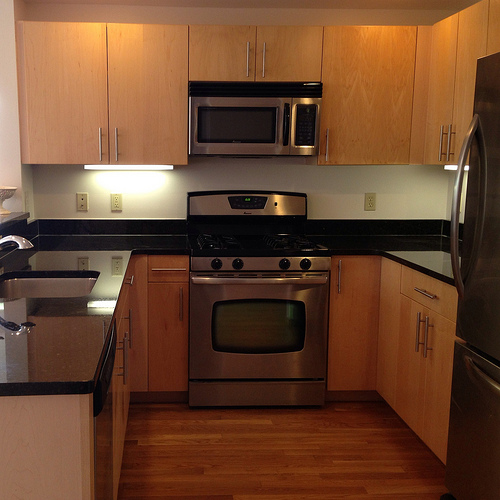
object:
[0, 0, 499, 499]
kitchen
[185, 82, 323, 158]
microwave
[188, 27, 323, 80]
cabinets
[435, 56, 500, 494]
refrigerator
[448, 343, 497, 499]
freezer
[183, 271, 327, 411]
oven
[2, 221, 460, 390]
counter top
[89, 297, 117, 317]
reflections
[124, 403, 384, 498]
floors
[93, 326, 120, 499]
dishwasher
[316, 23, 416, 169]
cabinet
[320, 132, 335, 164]
handles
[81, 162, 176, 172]
light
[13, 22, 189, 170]
cabinet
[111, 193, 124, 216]
outlet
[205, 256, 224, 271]
knobs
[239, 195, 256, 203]
writing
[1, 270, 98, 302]
sink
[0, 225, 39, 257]
faucet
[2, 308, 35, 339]
reflection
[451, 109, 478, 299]
handle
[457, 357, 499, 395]
handle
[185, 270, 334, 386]
door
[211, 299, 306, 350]
window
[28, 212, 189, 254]
counter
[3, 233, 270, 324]
counter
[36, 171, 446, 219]
wall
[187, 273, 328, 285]
handle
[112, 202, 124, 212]
sockets